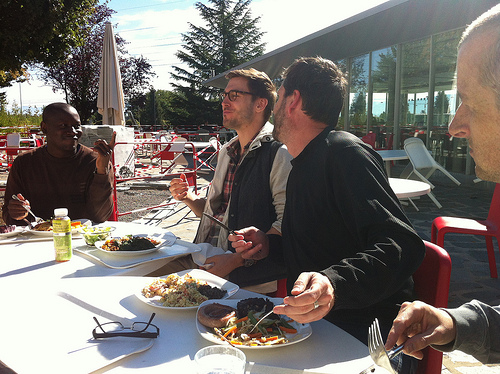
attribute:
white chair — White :
[402, 134, 460, 211]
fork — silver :
[357, 322, 406, 370]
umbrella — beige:
[90, 18, 130, 124]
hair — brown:
[292, 58, 346, 139]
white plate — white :
[28, 216, 92, 236]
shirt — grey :
[445, 295, 498, 365]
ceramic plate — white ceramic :
[97, 237, 164, 262]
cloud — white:
[129, 6, 166, 43]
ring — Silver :
[308, 299, 322, 316]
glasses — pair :
[90, 310, 161, 340]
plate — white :
[119, 238, 243, 307]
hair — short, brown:
[231, 62, 274, 113]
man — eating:
[6, 100, 118, 227]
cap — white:
[51, 203, 73, 217]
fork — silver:
[361, 314, 401, 371]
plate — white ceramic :
[191, 291, 316, 352]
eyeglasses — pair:
[92, 312, 162, 337]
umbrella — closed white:
[92, 17, 126, 123]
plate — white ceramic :
[147, 250, 251, 324]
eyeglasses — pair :
[84, 305, 174, 350]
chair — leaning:
[395, 132, 462, 214]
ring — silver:
[312, 301, 319, 308]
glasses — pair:
[85, 312, 164, 338]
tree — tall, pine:
[137, 0, 267, 123]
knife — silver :
[203, 212, 245, 241]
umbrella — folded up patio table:
[90, 15, 145, 132]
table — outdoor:
[0, 221, 380, 372]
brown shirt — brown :
[1, 140, 117, 222]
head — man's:
[271, 49, 340, 157]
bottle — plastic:
[49, 206, 78, 262]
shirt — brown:
[257, 126, 420, 331]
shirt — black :
[10, 140, 124, 210]